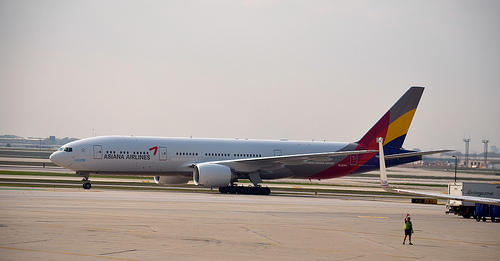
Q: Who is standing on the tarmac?
A: A person.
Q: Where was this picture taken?
A: An airport.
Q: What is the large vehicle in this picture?
A: An airplane.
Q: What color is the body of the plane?
A: White.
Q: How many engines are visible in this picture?
A: Two.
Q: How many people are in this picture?
A: One.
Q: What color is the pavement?
A: Grey.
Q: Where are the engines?
A: On the plane.